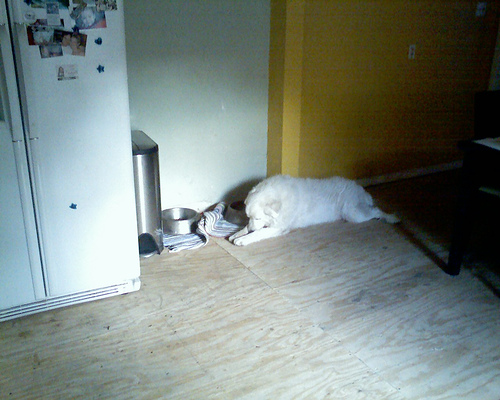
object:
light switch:
[475, 1, 489, 18]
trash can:
[130, 128, 166, 258]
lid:
[130, 129, 159, 155]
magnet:
[56, 61, 79, 81]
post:
[365, 330, 431, 346]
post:
[393, 376, 441, 388]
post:
[341, 370, 373, 387]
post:
[390, 367, 437, 377]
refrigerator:
[1, 0, 144, 320]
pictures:
[17, 3, 115, 81]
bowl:
[160, 208, 197, 236]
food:
[171, 216, 192, 224]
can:
[130, 125, 163, 257]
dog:
[221, 171, 399, 251]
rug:
[148, 208, 240, 253]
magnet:
[96, 64, 105, 73]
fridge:
[0, 2, 138, 328]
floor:
[4, 158, 483, 396]